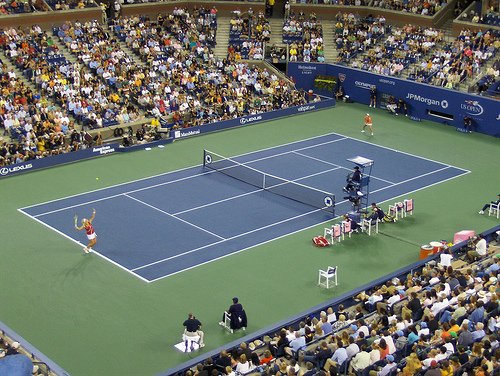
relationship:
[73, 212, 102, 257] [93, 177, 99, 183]
player hitting ball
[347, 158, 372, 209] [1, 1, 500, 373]
referee in stadium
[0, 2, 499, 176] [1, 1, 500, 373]
audience in stadium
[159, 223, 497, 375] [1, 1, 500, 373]
audience in stadium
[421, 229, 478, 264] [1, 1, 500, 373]
coolers in stadium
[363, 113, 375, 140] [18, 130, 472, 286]
player on court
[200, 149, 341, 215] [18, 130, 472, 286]
net on court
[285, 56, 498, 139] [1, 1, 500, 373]
sponsors in stadium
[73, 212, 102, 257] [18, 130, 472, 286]
player on court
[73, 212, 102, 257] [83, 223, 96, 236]
player wears red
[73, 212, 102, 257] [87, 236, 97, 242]
player wears white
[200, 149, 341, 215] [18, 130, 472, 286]
net in court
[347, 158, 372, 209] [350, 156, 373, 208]
referee in chair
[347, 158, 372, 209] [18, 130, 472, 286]
referee on court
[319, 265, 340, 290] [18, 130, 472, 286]
chair on court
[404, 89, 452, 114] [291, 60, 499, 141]
ad on wall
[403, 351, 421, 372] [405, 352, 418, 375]
person wearing yellow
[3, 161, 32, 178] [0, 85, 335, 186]
ad on wall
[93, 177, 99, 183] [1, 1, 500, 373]
ball in stadium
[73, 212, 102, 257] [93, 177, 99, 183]
player hits ball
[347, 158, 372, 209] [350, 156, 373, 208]
referee on chair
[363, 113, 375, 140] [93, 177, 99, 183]
player waiting for ball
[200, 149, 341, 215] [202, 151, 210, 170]
net on pole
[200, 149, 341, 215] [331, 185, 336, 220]
net on pole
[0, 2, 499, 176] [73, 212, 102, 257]
audience watches player